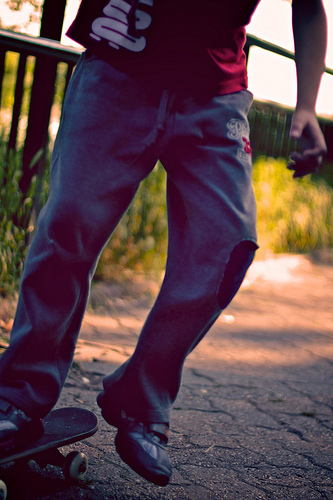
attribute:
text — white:
[89, 1, 156, 53]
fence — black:
[149, 71, 332, 172]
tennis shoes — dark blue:
[1, 398, 177, 487]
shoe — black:
[95, 384, 170, 483]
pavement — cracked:
[205, 385, 324, 453]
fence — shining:
[4, 36, 43, 104]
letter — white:
[90, 15, 147, 53]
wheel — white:
[67, 451, 88, 478]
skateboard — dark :
[4, 401, 101, 495]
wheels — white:
[61, 449, 90, 479]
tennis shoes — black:
[4, 344, 192, 470]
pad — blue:
[215, 236, 259, 316]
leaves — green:
[9, 0, 38, 32]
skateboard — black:
[0, 404, 99, 497]